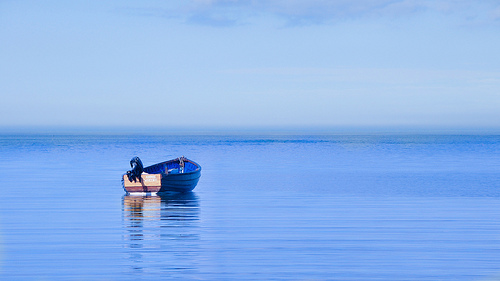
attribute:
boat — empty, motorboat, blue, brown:
[122, 156, 201, 196]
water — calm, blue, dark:
[1, 139, 499, 280]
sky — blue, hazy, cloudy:
[0, 0, 499, 133]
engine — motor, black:
[126, 156, 144, 182]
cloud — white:
[0, 65, 499, 125]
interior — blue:
[143, 161, 198, 174]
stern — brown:
[124, 174, 161, 197]